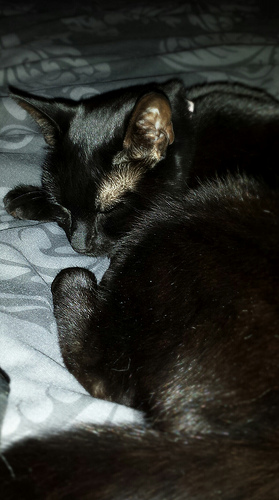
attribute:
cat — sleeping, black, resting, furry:
[3, 76, 278, 499]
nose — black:
[72, 243, 94, 257]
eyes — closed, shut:
[45, 193, 127, 222]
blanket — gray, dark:
[1, 0, 278, 448]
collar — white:
[172, 93, 200, 129]